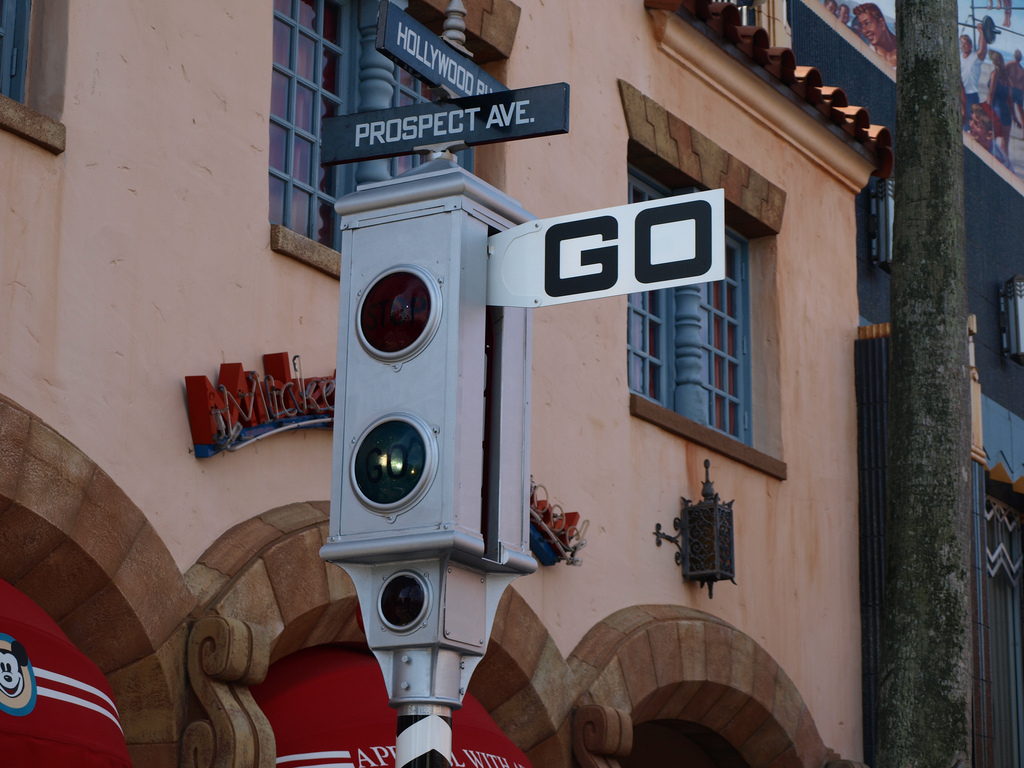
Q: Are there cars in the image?
A: No, there are no cars.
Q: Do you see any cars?
A: No, there are no cars.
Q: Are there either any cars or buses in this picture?
A: No, there are no cars or buses.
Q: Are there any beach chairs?
A: No, there are no beach chairs.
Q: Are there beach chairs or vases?
A: No, there are no beach chairs or vases.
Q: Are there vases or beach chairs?
A: No, there are no beach chairs or vases.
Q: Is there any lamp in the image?
A: Yes, there is a lamp.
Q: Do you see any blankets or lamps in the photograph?
A: Yes, there is a lamp.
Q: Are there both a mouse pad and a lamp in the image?
A: No, there is a lamp but no mouse pads.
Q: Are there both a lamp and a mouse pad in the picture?
A: No, there is a lamp but no mouse pads.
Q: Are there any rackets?
A: No, there are no rackets.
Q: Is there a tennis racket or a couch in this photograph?
A: No, there are no rackets or couches.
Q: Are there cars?
A: No, there are no cars.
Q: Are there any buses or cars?
A: No, there are no cars or buses.